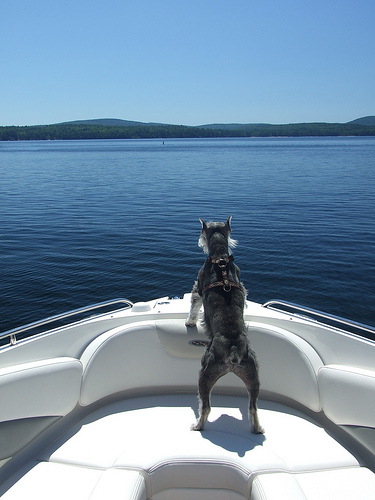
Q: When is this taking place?
A: Daytime.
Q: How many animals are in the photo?
A: One.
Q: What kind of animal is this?
A: Dog.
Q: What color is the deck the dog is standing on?
A: White.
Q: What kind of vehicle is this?
A: Boat.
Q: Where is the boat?
A: Water.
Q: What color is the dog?
A: Grey and white.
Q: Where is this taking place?
A: On a lake.